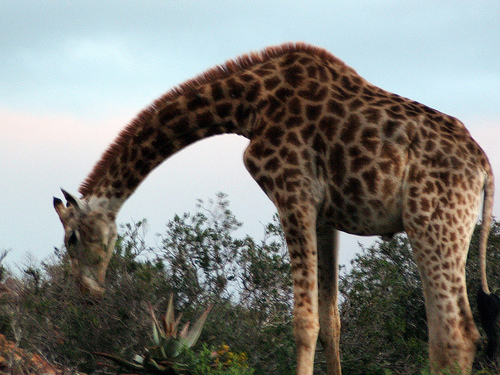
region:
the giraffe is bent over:
[52, 63, 356, 367]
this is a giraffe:
[35, 100, 399, 343]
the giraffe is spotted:
[254, 100, 446, 226]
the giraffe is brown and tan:
[264, 75, 453, 235]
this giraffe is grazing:
[71, 64, 450, 303]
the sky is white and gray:
[23, 15, 165, 214]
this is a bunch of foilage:
[121, 260, 273, 346]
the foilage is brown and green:
[146, 248, 255, 348]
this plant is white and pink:
[147, 274, 242, 364]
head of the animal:
[40, 183, 153, 293]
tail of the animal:
[477, 171, 497, 341]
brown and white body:
[286, 112, 436, 224]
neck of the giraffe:
[97, 96, 218, 202]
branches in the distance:
[147, 210, 267, 292]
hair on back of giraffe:
[98, 55, 236, 150]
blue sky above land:
[33, 20, 123, 85]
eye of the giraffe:
[52, 221, 93, 257]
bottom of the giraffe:
[331, 187, 405, 254]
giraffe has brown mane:
[32, 37, 269, 190]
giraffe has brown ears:
[36, 185, 107, 210]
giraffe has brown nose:
[57, 260, 122, 305]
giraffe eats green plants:
[22, 232, 209, 356]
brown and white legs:
[242, 208, 489, 359]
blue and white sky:
[0, 35, 155, 165]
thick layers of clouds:
[1, 7, 126, 160]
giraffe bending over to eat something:
[49, 38, 494, 371]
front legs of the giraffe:
[242, 133, 337, 373]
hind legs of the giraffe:
[415, 143, 490, 374]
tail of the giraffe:
[481, 146, 494, 294]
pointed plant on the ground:
[119, 287, 219, 370]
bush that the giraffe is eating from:
[0, 239, 148, 361]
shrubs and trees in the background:
[2, 191, 495, 373]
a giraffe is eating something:
[47, 46, 488, 372]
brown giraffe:
[27, 32, 498, 330]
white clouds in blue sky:
[424, 38, 496, 80]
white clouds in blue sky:
[384, 11, 429, 46]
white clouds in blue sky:
[185, 13, 245, 54]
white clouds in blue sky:
[55, 35, 102, 70]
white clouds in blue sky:
[95, 43, 142, 78]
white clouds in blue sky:
[32, 103, 64, 131]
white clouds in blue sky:
[37, 48, 89, 86]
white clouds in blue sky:
[25, 119, 70, 171]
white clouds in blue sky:
[170, 155, 231, 196]